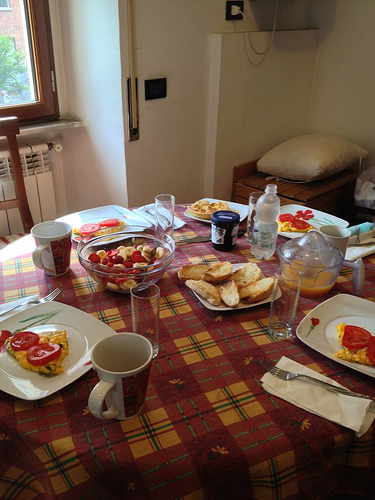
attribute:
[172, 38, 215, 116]
wall — white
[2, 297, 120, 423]
plate — White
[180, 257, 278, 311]
plate — White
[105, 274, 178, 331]
glass — Clear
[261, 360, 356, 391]
fork — Silver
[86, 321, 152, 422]
mug — White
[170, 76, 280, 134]
wall — White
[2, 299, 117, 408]
plate — White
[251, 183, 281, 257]
bottle — Clear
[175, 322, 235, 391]
tablecloth — red, orange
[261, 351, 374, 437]
napkin — White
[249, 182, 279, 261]
bottle — clear 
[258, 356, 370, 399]
fork — Silver